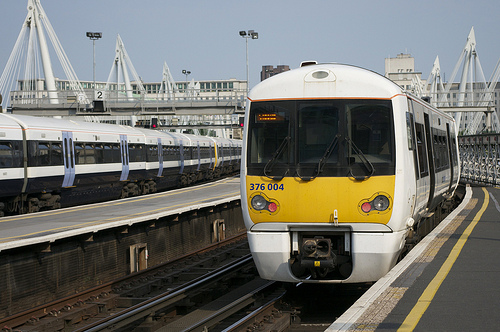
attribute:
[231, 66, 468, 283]
train — white, long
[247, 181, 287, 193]
number — blue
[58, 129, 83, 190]
door — blue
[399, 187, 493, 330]
line — yellow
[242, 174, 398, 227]
strip — yellow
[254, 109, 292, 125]
sign — black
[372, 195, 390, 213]
light — tall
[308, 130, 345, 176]
wiper — black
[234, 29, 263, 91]
light — tall, overhead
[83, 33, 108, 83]
light — tall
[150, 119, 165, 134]
light — red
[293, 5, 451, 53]
sky — blue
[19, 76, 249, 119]
building — white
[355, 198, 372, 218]
headlight — pink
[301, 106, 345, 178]
window — dark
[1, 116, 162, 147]
roof — white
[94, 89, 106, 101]
square — white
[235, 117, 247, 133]
light — red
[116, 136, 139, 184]
doors — blue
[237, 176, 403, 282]
front — yellow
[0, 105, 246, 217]
train — white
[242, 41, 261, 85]
pole — silver